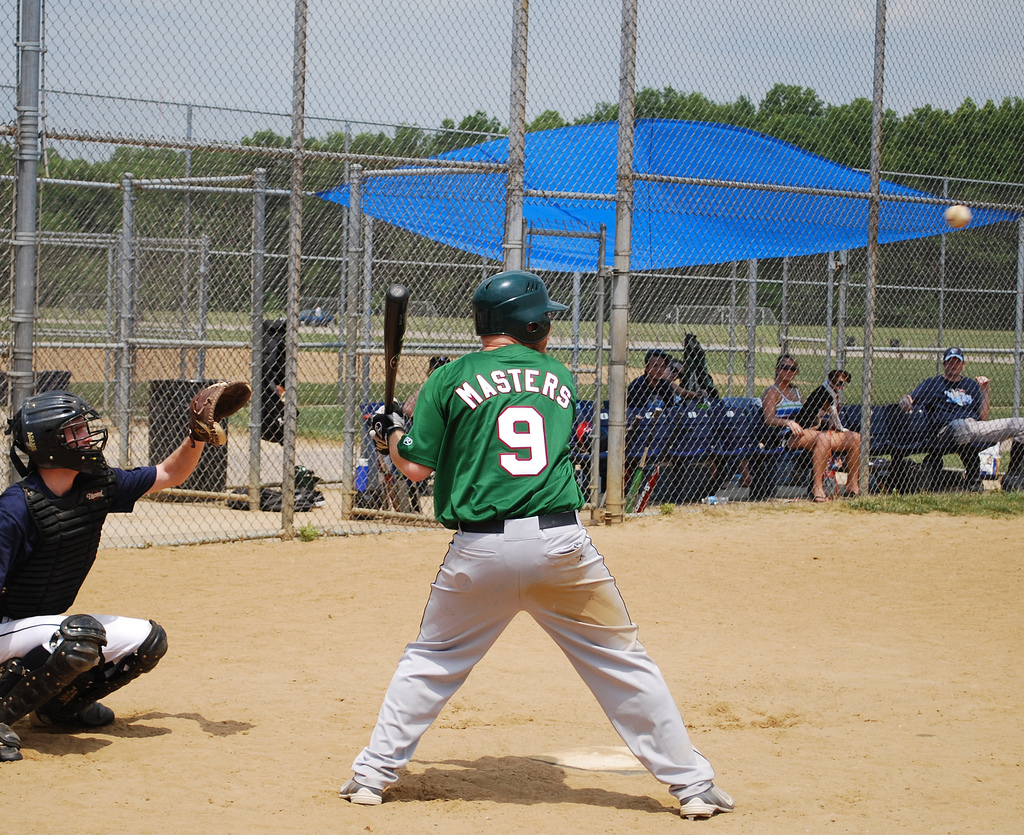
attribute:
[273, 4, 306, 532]
pole — metal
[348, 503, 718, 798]
pants — white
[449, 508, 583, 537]
belt — black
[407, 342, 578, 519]
jersey — green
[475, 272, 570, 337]
helmet — green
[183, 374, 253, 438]
glove — leather, brown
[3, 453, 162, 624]
shirt — blue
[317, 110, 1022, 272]
tarp — blue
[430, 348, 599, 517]
shirt — green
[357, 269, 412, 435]
bat — black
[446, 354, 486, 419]
letter — white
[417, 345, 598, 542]
jersey — green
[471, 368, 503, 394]
letter — white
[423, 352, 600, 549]
jersey — green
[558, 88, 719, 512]
posts — gray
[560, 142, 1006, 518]
fencing — chain link